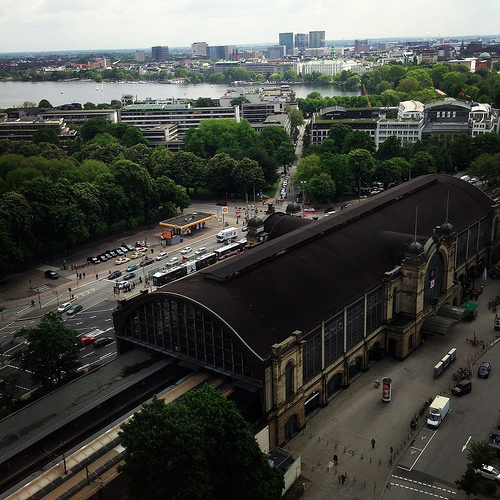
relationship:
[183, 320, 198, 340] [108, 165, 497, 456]
window on building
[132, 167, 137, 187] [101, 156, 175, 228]
leaf on plant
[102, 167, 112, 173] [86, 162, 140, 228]
leaf on plant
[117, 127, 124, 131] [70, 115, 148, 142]
leaf on plant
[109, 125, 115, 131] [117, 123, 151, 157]
leaf on plant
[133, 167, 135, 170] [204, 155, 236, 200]
lead on plant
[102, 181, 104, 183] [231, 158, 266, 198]
lead on plant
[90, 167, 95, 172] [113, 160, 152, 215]
lead on plant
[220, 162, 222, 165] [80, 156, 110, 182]
lead on plant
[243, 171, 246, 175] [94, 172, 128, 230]
lead on plant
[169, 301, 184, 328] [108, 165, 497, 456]
glass window on building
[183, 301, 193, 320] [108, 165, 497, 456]
window on building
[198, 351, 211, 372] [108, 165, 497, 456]
window on building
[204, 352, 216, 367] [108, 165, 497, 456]
window on building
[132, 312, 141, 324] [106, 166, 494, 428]
window on building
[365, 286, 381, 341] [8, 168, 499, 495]
window on building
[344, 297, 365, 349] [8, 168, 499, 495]
window on building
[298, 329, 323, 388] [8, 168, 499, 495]
window on building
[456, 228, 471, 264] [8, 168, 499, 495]
window on building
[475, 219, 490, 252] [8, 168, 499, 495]
window on building